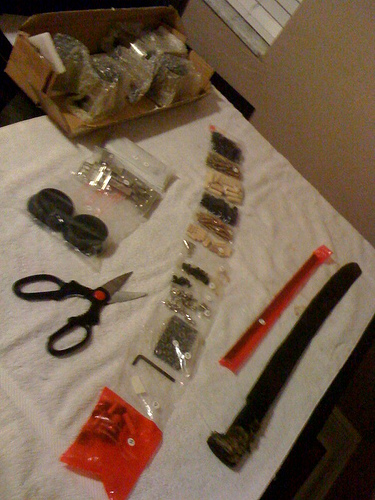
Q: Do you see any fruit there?
A: No, there are no fruits.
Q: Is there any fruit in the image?
A: No, there are no fruits.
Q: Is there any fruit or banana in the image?
A: No, there are no fruits or bananas.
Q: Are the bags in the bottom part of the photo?
A: Yes, the bags are in the bottom of the image.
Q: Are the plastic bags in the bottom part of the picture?
A: Yes, the bags are in the bottom of the image.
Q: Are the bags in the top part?
A: No, the bags are in the bottom of the image.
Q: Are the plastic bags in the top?
A: No, the bags are in the bottom of the image.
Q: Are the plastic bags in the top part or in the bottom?
A: The bags are in the bottom of the image.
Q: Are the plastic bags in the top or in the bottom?
A: The bags are in the bottom of the image.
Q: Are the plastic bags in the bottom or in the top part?
A: The bags are in the bottom of the image.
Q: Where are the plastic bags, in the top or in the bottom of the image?
A: The bags are in the bottom of the image.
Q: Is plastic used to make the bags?
A: Yes, the bags are made of plastic.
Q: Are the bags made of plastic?
A: Yes, the bags are made of plastic.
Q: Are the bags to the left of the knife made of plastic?
A: Yes, the bags are made of plastic.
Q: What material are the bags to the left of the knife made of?
A: The bags are made of plastic.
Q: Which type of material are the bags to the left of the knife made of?
A: The bags are made of plastic.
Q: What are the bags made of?
A: The bags are made of plastic.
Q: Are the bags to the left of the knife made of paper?
A: No, the bags are made of plastic.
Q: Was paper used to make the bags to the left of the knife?
A: No, the bags are made of plastic.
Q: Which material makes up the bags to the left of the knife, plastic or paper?
A: The bags are made of plastic.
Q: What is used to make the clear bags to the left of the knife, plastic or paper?
A: The bags are made of plastic.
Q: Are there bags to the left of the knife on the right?
A: Yes, there are bags to the left of the knife.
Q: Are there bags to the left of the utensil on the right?
A: Yes, there are bags to the left of the knife.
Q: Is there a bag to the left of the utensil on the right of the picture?
A: Yes, there are bags to the left of the knife.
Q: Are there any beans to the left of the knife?
A: No, there are bags to the left of the knife.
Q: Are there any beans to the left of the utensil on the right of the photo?
A: No, there are bags to the left of the knife.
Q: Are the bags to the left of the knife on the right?
A: Yes, the bags are to the left of the knife.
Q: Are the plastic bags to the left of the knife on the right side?
A: Yes, the bags are to the left of the knife.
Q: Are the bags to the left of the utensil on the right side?
A: Yes, the bags are to the left of the knife.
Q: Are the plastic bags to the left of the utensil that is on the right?
A: Yes, the bags are to the left of the knife.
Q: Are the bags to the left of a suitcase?
A: No, the bags are to the left of the knife.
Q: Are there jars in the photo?
A: No, there are no jars.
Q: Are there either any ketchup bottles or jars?
A: No, there are no jars or ketchup bottles.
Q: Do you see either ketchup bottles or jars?
A: No, there are no jars or ketchup bottles.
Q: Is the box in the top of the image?
A: Yes, the box is in the top of the image.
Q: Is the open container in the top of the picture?
A: Yes, the box is in the top of the image.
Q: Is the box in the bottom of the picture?
A: No, the box is in the top of the image.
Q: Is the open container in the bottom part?
A: No, the box is in the top of the image.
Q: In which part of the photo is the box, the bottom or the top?
A: The box is in the top of the image.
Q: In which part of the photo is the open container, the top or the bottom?
A: The box is in the top of the image.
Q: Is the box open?
A: Yes, the box is open.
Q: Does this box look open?
A: Yes, the box is open.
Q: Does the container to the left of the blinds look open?
A: Yes, the box is open.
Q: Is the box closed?
A: No, the box is open.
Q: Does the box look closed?
A: No, the box is open.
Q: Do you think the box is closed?
A: No, the box is open.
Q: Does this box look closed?
A: No, the box is open.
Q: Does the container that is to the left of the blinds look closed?
A: No, the box is open.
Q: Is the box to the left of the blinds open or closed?
A: The box is open.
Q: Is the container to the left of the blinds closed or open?
A: The box is open.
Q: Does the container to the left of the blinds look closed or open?
A: The box is open.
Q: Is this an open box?
A: Yes, this is an open box.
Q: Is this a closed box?
A: No, this is an open box.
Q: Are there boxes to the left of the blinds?
A: Yes, there is a box to the left of the blinds.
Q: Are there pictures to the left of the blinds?
A: No, there is a box to the left of the blinds.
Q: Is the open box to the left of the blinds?
A: Yes, the box is to the left of the blinds.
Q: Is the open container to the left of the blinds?
A: Yes, the box is to the left of the blinds.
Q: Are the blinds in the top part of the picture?
A: Yes, the blinds are in the top of the image.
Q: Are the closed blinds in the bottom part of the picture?
A: No, the blinds are in the top of the image.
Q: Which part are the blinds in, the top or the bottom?
A: The blinds are in the top of the image.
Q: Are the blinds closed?
A: Yes, the blinds are closed.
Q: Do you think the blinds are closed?
A: Yes, the blinds are closed.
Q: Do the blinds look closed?
A: Yes, the blinds are closed.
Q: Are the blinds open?
A: No, the blinds are closed.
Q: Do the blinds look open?
A: No, the blinds are closed.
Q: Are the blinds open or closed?
A: The blinds are closed.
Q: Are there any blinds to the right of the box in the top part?
A: Yes, there are blinds to the right of the box.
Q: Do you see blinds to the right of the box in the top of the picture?
A: Yes, there are blinds to the right of the box.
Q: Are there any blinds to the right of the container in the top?
A: Yes, there are blinds to the right of the box.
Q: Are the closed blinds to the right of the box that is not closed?
A: Yes, the blinds are to the right of the box.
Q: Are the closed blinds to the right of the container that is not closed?
A: Yes, the blinds are to the right of the box.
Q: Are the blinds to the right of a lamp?
A: No, the blinds are to the right of the box.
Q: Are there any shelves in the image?
A: No, there are no shelves.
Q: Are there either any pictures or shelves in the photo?
A: No, there are no shelves or pictures.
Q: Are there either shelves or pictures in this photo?
A: No, there are no shelves or pictures.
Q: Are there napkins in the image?
A: No, there are no napkins.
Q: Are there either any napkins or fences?
A: No, there are no napkins or fences.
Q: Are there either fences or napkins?
A: No, there are no napkins or fences.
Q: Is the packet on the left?
A: Yes, the packet is on the left of the image.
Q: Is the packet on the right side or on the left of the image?
A: The packet is on the left of the image.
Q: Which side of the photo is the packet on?
A: The packet is on the left of the image.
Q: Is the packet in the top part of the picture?
A: No, the packet is in the bottom of the image.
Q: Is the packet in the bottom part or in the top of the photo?
A: The packet is in the bottom of the image.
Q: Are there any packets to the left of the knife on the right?
A: Yes, there is a packet to the left of the knife.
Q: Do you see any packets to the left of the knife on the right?
A: Yes, there is a packet to the left of the knife.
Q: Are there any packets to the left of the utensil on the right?
A: Yes, there is a packet to the left of the knife.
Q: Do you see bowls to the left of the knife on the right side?
A: No, there is a packet to the left of the knife.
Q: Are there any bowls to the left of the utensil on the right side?
A: No, there is a packet to the left of the knife.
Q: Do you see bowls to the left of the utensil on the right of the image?
A: No, there is a packet to the left of the knife.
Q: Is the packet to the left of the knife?
A: Yes, the packet is to the left of the knife.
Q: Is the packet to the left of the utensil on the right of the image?
A: Yes, the packet is to the left of the knife.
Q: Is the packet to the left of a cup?
A: No, the packet is to the left of the knife.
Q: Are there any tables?
A: Yes, there is a table.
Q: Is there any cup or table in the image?
A: Yes, there is a table.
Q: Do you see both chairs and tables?
A: No, there is a table but no chairs.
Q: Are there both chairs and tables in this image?
A: No, there is a table but no chairs.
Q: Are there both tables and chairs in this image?
A: No, there is a table but no chairs.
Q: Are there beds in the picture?
A: No, there are no beds.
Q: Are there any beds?
A: No, there are no beds.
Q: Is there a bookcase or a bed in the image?
A: No, there are no beds or bookcases.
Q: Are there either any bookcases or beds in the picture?
A: No, there are no beds or bookcases.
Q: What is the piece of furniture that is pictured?
A: The piece of furniture is a table.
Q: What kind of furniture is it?
A: The piece of furniture is a table.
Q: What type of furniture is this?
A: That is a table.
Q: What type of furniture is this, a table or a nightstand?
A: That is a table.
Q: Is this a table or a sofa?
A: This is a table.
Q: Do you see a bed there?
A: No, there are no beds.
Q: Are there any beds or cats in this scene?
A: No, there are no beds or cats.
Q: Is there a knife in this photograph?
A: Yes, there is a knife.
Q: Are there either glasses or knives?
A: Yes, there is a knife.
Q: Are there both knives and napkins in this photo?
A: No, there is a knife but no napkins.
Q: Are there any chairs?
A: No, there are no chairs.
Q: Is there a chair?
A: No, there are no chairs.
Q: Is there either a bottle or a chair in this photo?
A: No, there are no chairs or bottles.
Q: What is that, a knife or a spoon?
A: That is a knife.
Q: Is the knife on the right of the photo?
A: Yes, the knife is on the right of the image.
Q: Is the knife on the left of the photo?
A: No, the knife is on the right of the image.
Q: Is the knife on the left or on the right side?
A: The knife is on the right of the image.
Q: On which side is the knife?
A: The knife is on the right of the image.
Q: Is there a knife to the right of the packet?
A: Yes, there is a knife to the right of the packet.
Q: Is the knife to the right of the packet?
A: Yes, the knife is to the right of the packet.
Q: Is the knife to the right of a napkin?
A: No, the knife is to the right of the packet.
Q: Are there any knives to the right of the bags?
A: Yes, there is a knife to the right of the bags.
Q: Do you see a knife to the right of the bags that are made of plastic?
A: Yes, there is a knife to the right of the bags.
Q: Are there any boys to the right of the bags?
A: No, there is a knife to the right of the bags.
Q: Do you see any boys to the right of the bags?
A: No, there is a knife to the right of the bags.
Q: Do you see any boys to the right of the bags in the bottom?
A: No, there is a knife to the right of the bags.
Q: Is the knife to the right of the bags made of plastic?
A: Yes, the knife is to the right of the bags.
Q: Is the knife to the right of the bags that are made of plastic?
A: Yes, the knife is to the right of the bags.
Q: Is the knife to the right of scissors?
A: No, the knife is to the right of the bags.